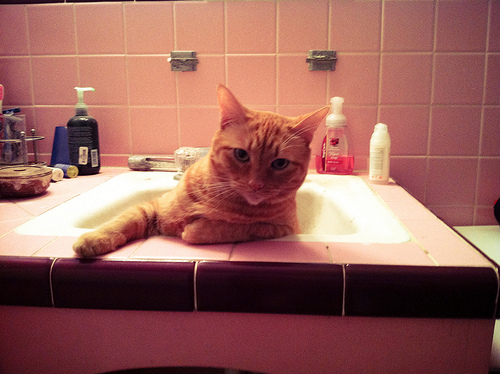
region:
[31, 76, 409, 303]
Tabby cat in the sink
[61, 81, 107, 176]
Liquid soap dispense on counter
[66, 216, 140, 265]
Cat's paw on the sink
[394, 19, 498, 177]
Pink tile on the wall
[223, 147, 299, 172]
Cat's green eyes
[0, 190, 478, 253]
Pink tile around white sink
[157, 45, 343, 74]
Bolts for a towel holder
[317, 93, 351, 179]
Liquid soap on the counter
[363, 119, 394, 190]
White plastic bottle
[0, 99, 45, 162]
Silver-plated toothbrush holder on the counter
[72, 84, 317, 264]
the cat in the sink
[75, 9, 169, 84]
the pink tiles on the wall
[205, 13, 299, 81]
the tiles on the wall behind the cat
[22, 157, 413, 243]
the white sink the cat is lying in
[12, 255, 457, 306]
the darker tiles near the cat's paw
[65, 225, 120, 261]
the cat's paw resting on the tile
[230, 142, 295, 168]
the cat's two eyes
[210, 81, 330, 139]
the cat's two ears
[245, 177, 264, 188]
the cat's little nose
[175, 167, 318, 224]
the whiskers near the cat's nose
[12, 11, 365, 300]
an orange cat in sink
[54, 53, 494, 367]
a cat in sink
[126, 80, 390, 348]
an orange cat inside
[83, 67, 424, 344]
an cat that is inside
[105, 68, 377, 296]
an orange striped cat in sink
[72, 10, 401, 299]
an orange striped cat inside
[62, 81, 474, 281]
a sink with cat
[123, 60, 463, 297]
a sink with orange cat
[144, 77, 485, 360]
a sink with orange striped cat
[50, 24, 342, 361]
a white bathroom sink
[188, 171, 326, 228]
the whiskers on the cat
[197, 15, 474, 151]
the wall is pink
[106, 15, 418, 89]
the wall is tiled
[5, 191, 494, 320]
the vanity is tiled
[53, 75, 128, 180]
the black soap dispenser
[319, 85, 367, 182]
the pink soap dispenser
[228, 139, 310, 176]
the eyes of the cat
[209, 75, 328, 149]
the ears of the cat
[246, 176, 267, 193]
the nose of the cat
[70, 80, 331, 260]
Cat sitting in white sink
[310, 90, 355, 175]
Soap bottle next to faucet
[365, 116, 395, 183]
Small white bottle next to soap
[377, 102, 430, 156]
Pink tile on wall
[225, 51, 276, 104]
Pink tile on wall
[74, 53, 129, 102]
Pink tile on wall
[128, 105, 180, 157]
Pink tile on wall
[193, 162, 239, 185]
White whisker on cat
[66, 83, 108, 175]
Black bottle facing the wall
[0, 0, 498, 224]
Wall is pink